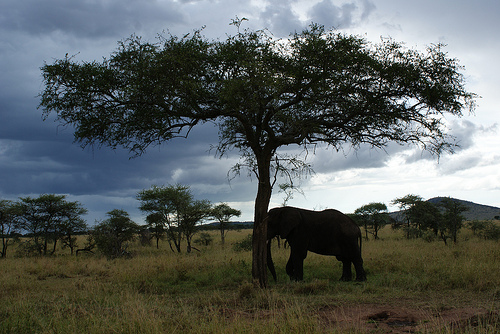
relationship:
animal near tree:
[270, 204, 371, 286] [47, 34, 387, 174]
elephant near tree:
[270, 204, 371, 286] [47, 34, 387, 174]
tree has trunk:
[47, 34, 387, 174] [250, 163, 276, 216]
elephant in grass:
[270, 204, 371, 286] [393, 270, 414, 290]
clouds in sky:
[40, 15, 58, 31] [44, 14, 82, 35]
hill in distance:
[473, 209, 484, 220] [453, 193, 469, 209]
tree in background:
[388, 194, 419, 208] [396, 202, 417, 218]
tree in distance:
[388, 194, 419, 208] [453, 193, 469, 209]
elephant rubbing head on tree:
[270, 204, 371, 286] [47, 34, 387, 174]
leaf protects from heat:
[211, 89, 222, 111] [204, 127, 212, 134]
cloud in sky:
[458, 24, 482, 44] [44, 14, 82, 35]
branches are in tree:
[111, 42, 155, 80] [47, 34, 387, 174]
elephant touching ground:
[270, 204, 371, 286] [310, 283, 340, 296]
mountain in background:
[472, 207, 489, 218] [396, 202, 417, 218]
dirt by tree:
[143, 290, 165, 306] [47, 34, 387, 174]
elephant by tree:
[270, 204, 371, 286] [47, 34, 387, 174]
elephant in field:
[270, 204, 371, 286] [273, 283, 419, 333]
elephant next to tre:
[270, 204, 371, 286] [47, 34, 387, 174]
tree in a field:
[47, 34, 387, 174] [273, 283, 419, 333]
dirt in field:
[143, 290, 165, 306] [273, 283, 419, 333]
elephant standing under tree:
[270, 204, 371, 286] [47, 34, 387, 174]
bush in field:
[98, 221, 132, 254] [273, 283, 419, 333]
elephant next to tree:
[270, 204, 371, 286] [47, 34, 387, 174]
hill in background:
[473, 209, 484, 220] [396, 202, 417, 218]